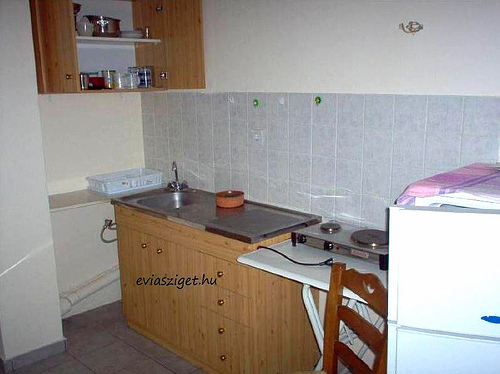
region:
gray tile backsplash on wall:
[206, 94, 426, 160]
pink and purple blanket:
[405, 154, 498, 203]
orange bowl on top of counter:
[215, 179, 246, 215]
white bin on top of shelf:
[101, 165, 170, 197]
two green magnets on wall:
[233, 76, 342, 123]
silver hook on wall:
[386, 12, 435, 42]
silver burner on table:
[286, 208, 417, 280]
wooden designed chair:
[327, 269, 397, 366]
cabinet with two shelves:
[63, 6, 162, 113]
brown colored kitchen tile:
[106, 316, 142, 371]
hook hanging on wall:
[395, 19, 427, 36]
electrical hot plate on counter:
[287, 212, 393, 270]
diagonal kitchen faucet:
[164, 163, 190, 191]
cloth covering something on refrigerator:
[398, 161, 496, 211]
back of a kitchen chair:
[324, 258, 403, 372]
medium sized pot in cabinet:
[82, 11, 122, 37]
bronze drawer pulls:
[210, 260, 233, 365]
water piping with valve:
[94, 216, 123, 243]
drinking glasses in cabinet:
[100, 66, 154, 88]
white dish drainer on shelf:
[82, 164, 167, 195]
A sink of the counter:
[140, 160, 203, 215]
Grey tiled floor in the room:
[87, 334, 132, 364]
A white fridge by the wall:
[396, 170, 498, 372]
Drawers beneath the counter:
[205, 267, 250, 367]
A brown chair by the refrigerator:
[328, 261, 386, 371]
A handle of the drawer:
[213, 296, 230, 306]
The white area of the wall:
[262, 28, 367, 70]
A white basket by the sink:
[82, 165, 162, 187]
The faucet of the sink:
[161, 163, 188, 188]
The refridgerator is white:
[424, 248, 480, 283]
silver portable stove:
[291, 215, 390, 269]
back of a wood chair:
[320, 260, 388, 370]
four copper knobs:
[208, 259, 235, 372]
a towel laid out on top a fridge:
[393, 160, 498, 209]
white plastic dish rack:
[82, 162, 165, 194]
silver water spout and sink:
[125, 157, 209, 217]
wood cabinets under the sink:
[109, 170, 310, 371]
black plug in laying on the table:
[253, 240, 347, 278]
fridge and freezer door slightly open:
[377, 175, 498, 372]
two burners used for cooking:
[312, 216, 389, 262]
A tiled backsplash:
[147, 93, 394, 200]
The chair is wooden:
[332, 264, 386, 371]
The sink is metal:
[136, 165, 204, 217]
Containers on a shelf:
[82, 68, 177, 92]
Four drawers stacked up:
[203, 256, 255, 371]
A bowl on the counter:
[213, 191, 247, 211]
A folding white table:
[254, 242, 389, 371]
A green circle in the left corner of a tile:
[313, 95, 337, 122]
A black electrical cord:
[260, 243, 333, 265]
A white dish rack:
[87, 170, 164, 193]